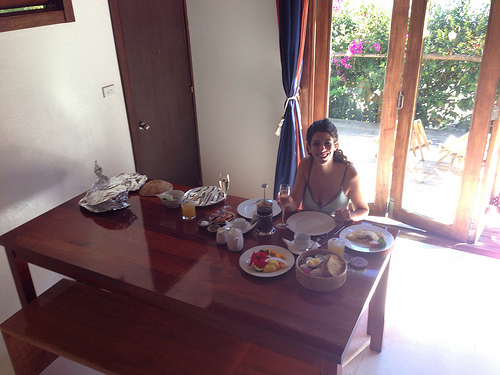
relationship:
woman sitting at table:
[282, 119, 369, 221] [1, 175, 401, 374]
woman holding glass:
[282, 119, 369, 221] [279, 184, 289, 227]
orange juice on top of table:
[182, 199, 196, 218] [1, 175, 401, 374]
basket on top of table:
[295, 249, 348, 291] [1, 175, 401, 374]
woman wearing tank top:
[282, 119, 369, 221] [301, 160, 352, 216]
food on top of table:
[249, 247, 289, 272] [1, 175, 401, 374]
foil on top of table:
[80, 160, 147, 213] [1, 175, 401, 374]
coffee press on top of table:
[255, 184, 276, 236] [1, 175, 401, 374]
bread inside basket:
[327, 256, 343, 276] [295, 249, 348, 291]